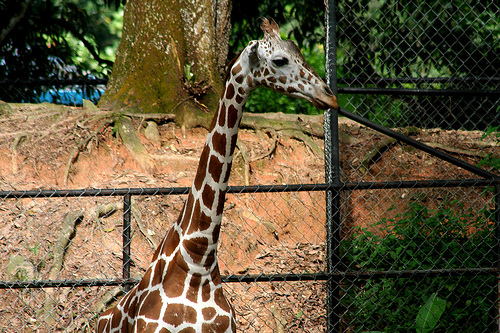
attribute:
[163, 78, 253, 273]
neck — long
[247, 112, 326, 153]
roots — tree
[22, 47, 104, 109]
bluecar — blue, bright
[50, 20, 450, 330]
giraffe — standing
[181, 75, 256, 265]
neck — long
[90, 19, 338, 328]
giraffe — long necked, white and brown, spotted, sad, tall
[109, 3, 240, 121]
tree trunk — covered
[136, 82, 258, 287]
neck — long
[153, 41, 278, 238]
giraffe neck — long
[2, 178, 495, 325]
poles — metal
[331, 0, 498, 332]
fence — tall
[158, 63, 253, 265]
neck — long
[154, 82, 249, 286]
neck — narrow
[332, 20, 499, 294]
fence — chain, link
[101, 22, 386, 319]
giraffe — sitting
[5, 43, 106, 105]
pool — hidden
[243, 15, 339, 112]
head — narrow, pointy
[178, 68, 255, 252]
neck — long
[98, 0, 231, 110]
tree trunk — big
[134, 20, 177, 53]
spots — white